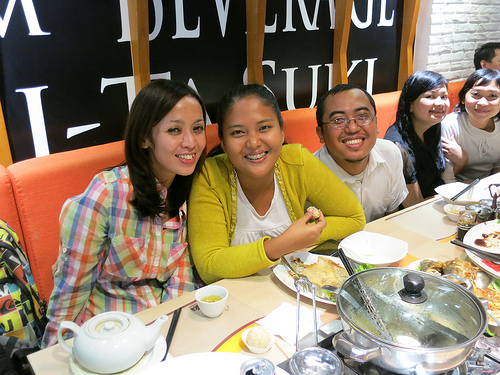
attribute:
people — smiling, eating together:
[40, 67, 499, 350]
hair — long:
[397, 71, 445, 192]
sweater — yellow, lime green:
[189, 145, 363, 284]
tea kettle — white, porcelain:
[57, 311, 170, 373]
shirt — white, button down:
[314, 140, 408, 222]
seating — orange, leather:
[2, 81, 475, 305]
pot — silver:
[333, 268, 488, 373]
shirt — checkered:
[42, 168, 197, 348]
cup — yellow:
[196, 284, 225, 319]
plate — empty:
[339, 232, 408, 267]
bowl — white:
[434, 181, 484, 206]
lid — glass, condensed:
[340, 268, 486, 346]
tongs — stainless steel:
[452, 239, 499, 261]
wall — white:
[414, 1, 498, 87]